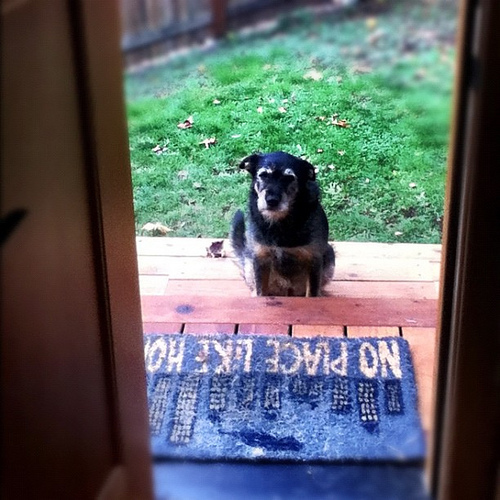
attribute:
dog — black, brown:
[227, 150, 334, 296]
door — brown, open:
[0, 1, 158, 498]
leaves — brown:
[326, 47, 430, 85]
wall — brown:
[1, 0, 153, 498]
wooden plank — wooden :
[143, 294, 443, 326]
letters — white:
[146, 338, 404, 381]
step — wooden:
[134, 222, 494, 394]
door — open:
[38, 22, 195, 454]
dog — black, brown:
[178, 147, 370, 356]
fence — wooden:
[122, 22, 289, 66]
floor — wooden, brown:
[135, 236, 442, 498]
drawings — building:
[147, 368, 424, 469]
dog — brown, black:
[175, 109, 380, 308]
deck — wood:
[136, 234, 443, 492]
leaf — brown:
[176, 115, 194, 133]